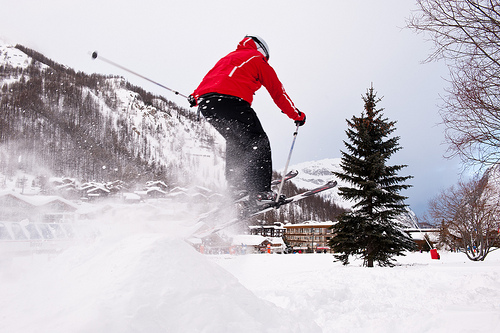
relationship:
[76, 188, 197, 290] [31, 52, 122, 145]
snow on mountain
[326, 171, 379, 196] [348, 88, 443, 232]
branch on evegreen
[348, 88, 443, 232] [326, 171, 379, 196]
evegreen has branch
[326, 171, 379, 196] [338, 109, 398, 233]
branch of tree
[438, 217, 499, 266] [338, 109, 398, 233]
trunks on tree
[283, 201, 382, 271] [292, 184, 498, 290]
bulidings in background